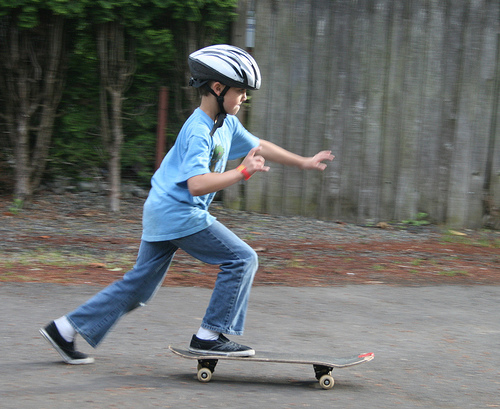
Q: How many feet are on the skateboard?
A: 1.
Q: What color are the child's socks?
A: White.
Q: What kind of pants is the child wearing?
A: Blue jeans.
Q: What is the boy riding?
A: Skateboard.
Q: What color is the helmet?
A: Black and white.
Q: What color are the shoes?
A: Black.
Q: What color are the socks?
A: White.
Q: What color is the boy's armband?
A: Orange.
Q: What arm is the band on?
A: The right.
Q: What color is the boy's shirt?
A: Light blue.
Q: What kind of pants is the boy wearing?
A: Blue jeans.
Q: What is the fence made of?
A: Wood.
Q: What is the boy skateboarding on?
A: Roadway.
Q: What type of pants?
A: Blue jean.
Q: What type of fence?
A: Wooden.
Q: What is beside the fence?
A: Trees.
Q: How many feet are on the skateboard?
A: One.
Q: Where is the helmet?
A: Boy's head.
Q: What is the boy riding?
A: Skateboard.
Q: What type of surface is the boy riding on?
A: Concrete.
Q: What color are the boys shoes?
A: Black.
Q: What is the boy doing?
A: Skateboarding.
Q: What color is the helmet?
A: White and black.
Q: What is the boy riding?
A: A skateboard.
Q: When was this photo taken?
A: During the day.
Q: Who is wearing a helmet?
A: The boy.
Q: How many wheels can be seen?
A: Two.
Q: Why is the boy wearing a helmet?
A: Safety.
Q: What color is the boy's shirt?
A: Blue.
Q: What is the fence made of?
A: Wood.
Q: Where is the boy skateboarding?
A: On a street.